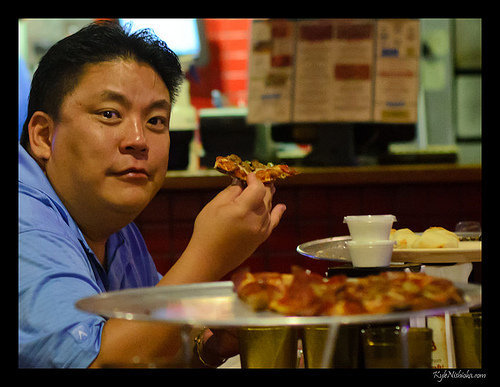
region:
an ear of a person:
[24, 106, 58, 161]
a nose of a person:
[120, 114, 155, 161]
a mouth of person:
[109, 161, 160, 184]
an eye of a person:
[89, 104, 124, 124]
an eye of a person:
[146, 106, 169, 136]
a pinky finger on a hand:
[271, 192, 293, 229]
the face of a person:
[79, 56, 171, 210]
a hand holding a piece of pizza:
[214, 148, 296, 188]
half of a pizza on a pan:
[103, 255, 477, 336]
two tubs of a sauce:
[342, 207, 399, 264]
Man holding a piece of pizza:
[24, 53, 295, 236]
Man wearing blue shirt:
[21, 63, 174, 368]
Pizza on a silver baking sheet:
[68, 271, 479, 342]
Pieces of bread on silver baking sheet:
[395, 208, 497, 275]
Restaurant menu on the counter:
[238, 20, 444, 142]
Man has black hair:
[20, 20, 202, 185]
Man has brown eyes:
[70, 91, 182, 136]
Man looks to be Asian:
[29, 37, 179, 226]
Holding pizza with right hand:
[203, 136, 295, 252]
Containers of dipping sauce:
[328, 198, 416, 273]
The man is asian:
[60, 77, 194, 199]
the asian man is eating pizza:
[86, 53, 316, 214]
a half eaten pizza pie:
[178, 225, 473, 340]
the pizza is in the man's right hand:
[192, 148, 309, 273]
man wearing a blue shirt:
[13, 150, 206, 370]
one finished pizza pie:
[277, 194, 494, 276]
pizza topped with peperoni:
[133, 240, 469, 332]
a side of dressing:
[333, 212, 419, 281]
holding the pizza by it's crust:
[208, 164, 313, 224]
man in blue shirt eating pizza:
[37, 39, 369, 313]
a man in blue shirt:
[27, 20, 227, 286]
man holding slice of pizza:
[25, 22, 297, 232]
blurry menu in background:
[237, 15, 453, 147]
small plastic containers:
[325, 187, 401, 272]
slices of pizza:
[227, 262, 453, 334]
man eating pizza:
[35, 25, 295, 275]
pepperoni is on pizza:
[215, 257, 462, 322]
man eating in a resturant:
[27, 25, 457, 352]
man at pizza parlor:
[32, 27, 464, 357]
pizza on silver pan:
[60, 269, 496, 334]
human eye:
[87, 103, 125, 125]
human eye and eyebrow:
[80, 86, 133, 126]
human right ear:
[24, 106, 57, 163]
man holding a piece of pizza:
[19, 20, 293, 368]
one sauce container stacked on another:
[336, 204, 399, 272]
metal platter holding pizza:
[73, 266, 475, 328]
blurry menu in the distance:
[241, 18, 433, 149]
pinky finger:
[269, 201, 289, 239]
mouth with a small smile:
[96, 160, 158, 190]